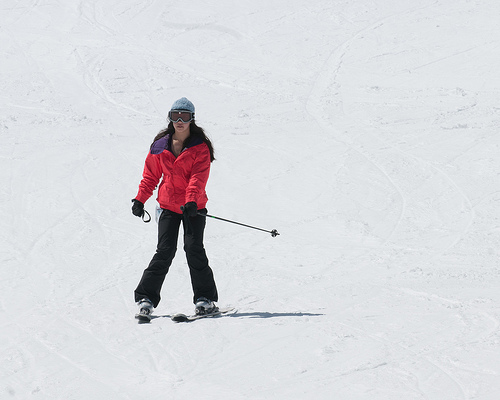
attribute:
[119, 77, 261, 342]
skier — female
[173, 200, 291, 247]
ski pole — black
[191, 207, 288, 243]
ski pole — black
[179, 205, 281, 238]
pole — snowy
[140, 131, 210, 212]
jacket — purple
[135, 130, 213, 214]
coat — red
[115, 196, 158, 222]
glove — black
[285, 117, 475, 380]
snow — White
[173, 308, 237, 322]
ski — White 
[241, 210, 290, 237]
pole — black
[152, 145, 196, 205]
jacket — red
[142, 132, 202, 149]
hood — purple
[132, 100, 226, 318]
woman — alone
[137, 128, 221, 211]
coat — red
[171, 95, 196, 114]
beanie — blue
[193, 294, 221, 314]
ski shoe — white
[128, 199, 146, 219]
glove — black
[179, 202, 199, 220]
glove — black